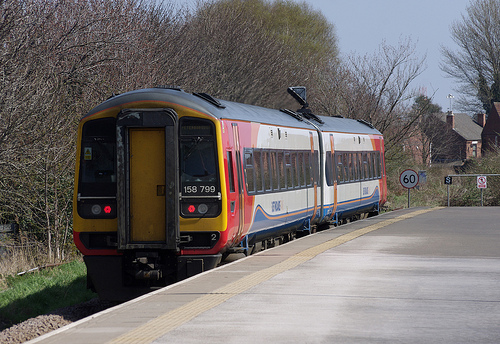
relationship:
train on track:
[50, 83, 393, 270] [67, 288, 124, 322]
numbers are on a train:
[181, 176, 226, 202] [50, 95, 402, 248]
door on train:
[124, 126, 172, 242] [89, 65, 435, 260]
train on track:
[50, 83, 393, 270] [6, 194, 436, 341]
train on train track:
[50, 83, 393, 270] [0, 292, 115, 332]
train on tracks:
[50, 61, 420, 271] [0, 200, 444, 341]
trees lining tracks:
[0, 7, 332, 91] [68, 81, 396, 258]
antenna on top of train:
[286, 82, 323, 122] [68, 87, 388, 244]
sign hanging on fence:
[476, 176, 486, 187] [446, 172, 499, 206]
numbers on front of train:
[181, 180, 217, 198] [72, 99, 397, 216]